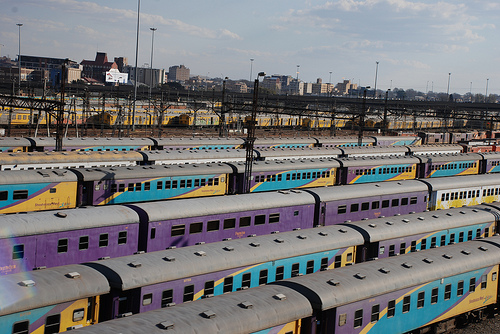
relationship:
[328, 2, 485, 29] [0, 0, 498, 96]
cloud in sky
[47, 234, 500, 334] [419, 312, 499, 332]
train on tracks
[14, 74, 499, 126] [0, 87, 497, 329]
tracks with trains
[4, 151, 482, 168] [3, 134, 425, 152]
train with train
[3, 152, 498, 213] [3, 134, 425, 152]
train with train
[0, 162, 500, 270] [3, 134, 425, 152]
train with train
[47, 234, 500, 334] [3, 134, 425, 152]
train with train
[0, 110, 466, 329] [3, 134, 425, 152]
area with train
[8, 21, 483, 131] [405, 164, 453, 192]
metropolis in ground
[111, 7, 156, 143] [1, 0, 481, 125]
poles in background